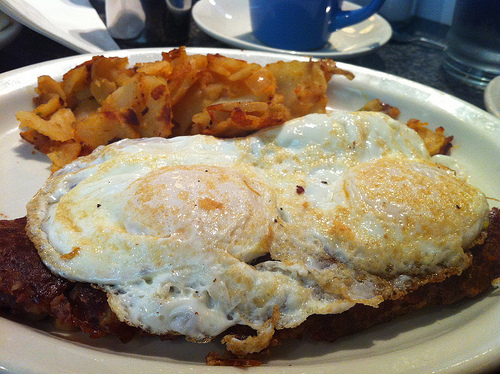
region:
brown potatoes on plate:
[35, 44, 325, 159]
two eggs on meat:
[97, 129, 452, 249]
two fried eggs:
[58, 117, 419, 294]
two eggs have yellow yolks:
[117, 143, 416, 265]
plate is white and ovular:
[3, 70, 495, 348]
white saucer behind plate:
[200, 2, 403, 79]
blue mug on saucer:
[216, 0, 382, 63]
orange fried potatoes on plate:
[9, 52, 321, 159]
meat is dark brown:
[14, 207, 497, 359]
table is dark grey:
[373, 8, 463, 95]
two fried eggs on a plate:
[20, 147, 471, 308]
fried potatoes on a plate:
[0, 56, 310, 149]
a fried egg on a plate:
[35, 139, 286, 291]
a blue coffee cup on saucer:
[239, 7, 384, 51]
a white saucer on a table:
[172, 11, 391, 51]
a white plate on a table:
[31, 75, 454, 372]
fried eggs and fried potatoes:
[18, 62, 375, 272]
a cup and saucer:
[214, 2, 380, 52]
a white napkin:
[10, 5, 100, 65]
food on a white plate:
[0, 48, 466, 314]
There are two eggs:
[37, 108, 480, 342]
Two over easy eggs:
[17, 133, 475, 342]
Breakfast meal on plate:
[11, 61, 493, 363]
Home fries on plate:
[27, 33, 348, 163]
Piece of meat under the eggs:
[10, 196, 499, 361]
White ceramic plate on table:
[5, 46, 496, 366]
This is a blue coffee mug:
[250, 0, 394, 49]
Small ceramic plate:
[176, 0, 391, 55]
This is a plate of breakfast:
[28, 33, 488, 372]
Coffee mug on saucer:
[190, 0, 397, 55]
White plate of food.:
[5, 45, 495, 355]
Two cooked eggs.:
[34, 117, 492, 294]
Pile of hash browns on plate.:
[27, 42, 337, 157]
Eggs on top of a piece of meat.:
[2, 107, 493, 368]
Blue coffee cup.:
[237, 2, 384, 48]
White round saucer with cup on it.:
[181, 0, 396, 59]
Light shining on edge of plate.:
[357, 64, 493, 118]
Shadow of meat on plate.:
[91, 309, 491, 371]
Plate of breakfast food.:
[7, 40, 491, 364]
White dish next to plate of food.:
[475, 64, 498, 121]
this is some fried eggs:
[173, 127, 336, 277]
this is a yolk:
[150, 188, 245, 201]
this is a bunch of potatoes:
[55, 56, 134, 103]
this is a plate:
[369, 331, 406, 354]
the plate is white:
[384, 338, 401, 367]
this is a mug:
[302, 14, 353, 61]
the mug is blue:
[268, 20, 378, 47]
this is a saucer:
[235, 16, 236, 42]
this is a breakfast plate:
[41, 53, 234, 313]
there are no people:
[130, 176, 379, 334]